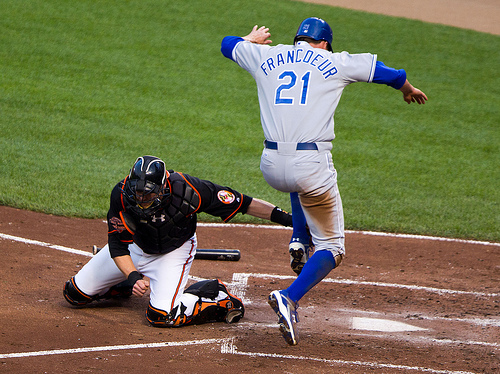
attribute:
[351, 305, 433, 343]
home plate — white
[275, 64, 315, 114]
number — twenty one, 21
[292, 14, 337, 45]
helmet — blue, dark blue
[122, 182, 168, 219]
mask — black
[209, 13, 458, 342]
man — trying, jumping, leaping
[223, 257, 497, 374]
batters box — used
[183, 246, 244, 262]
bat — black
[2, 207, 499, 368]
dirt — brown, dirt covered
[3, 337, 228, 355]
chalk line — white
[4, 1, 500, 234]
grass — green, dense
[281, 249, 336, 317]
socks — blue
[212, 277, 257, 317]
sneaker — orange, blue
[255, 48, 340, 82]
name — curved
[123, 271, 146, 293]
wristband — black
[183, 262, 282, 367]
lines — white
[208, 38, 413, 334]
uniform — gray, blue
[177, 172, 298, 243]
arm — outstretched, extended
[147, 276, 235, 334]
pads — orange, black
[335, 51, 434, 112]
arm — outstretched, lifted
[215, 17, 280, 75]
arm — outstretched, lifted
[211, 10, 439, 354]
player — running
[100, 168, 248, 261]
jersey — black, orange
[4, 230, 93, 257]
line — white